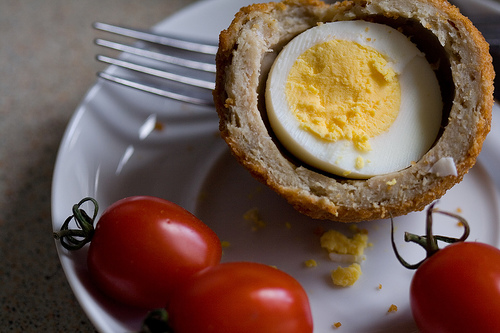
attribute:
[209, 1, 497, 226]
food — breakfast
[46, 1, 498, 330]
plate — full, white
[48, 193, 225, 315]
food — breakfast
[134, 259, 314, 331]
food — breakfast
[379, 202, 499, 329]
food — breakfast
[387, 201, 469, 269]
stem — green, leafy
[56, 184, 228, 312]
tomato — juicy, red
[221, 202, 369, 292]
crumbs — wayward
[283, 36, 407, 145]
yolk — hard , boiled , a egg yolk 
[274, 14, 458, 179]
egg — yellow , hard , boiled , a yolk 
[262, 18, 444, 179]
egg — yellow, hard , boiled 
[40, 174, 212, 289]
tomato — shiny, ripe, red, a cherry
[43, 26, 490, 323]
plate — white 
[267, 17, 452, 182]
egg white — hard, boiled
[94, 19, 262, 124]
fork — metal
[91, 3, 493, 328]
breakfast — petite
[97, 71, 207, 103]
tines — silver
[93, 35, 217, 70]
tines — silver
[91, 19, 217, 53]
tines — silver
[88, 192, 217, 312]
tomato — shiny, ripe, red, cherry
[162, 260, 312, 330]
tomato — shiny, ripe, red, a cherry